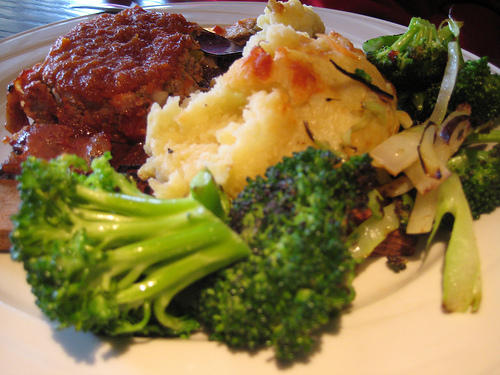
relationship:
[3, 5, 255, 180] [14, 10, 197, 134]
tomato sauce on meatloaf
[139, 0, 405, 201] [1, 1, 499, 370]
mash potatoes in middle of dish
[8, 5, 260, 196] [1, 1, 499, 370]
stew on dish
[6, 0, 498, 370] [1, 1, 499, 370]
meal on dish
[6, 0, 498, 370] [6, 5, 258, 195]
meal has meat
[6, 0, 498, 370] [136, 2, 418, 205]
meal has mash potatoes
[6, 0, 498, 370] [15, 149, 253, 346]
meal has broccoli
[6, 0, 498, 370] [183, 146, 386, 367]
meal has broccoli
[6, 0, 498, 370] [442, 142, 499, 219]
meal has broccoli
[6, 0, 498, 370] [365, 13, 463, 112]
meal has broccoli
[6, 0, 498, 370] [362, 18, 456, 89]
meal has broccoli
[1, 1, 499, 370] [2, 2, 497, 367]
dish has food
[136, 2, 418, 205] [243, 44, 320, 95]
mash potatoes have spots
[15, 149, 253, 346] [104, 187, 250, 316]
broccoli has stem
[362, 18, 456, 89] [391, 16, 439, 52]
broccoli has stem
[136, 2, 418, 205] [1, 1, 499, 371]
mash potatoes on plate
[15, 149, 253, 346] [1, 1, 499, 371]
broccoli crown on plate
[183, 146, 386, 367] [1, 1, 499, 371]
broccoli crown on plate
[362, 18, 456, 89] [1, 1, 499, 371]
broccoli crown on plate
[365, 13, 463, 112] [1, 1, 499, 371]
broccoli on plate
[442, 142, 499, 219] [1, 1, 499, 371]
broccoli crown on plate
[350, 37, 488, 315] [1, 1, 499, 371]
onions on plate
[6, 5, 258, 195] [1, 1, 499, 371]
meat on plate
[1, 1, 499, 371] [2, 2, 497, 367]
plate has food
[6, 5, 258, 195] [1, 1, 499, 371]
mince meat on plate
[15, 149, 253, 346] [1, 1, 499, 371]
broccoli crown around plate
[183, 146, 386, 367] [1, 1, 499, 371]
broccoli crown around plate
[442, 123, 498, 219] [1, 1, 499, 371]
broccoli crown around plate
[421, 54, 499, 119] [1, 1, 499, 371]
broccoli crown around plate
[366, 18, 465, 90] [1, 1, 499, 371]
broccoli crown around plate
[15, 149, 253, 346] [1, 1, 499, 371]
broccoli on plate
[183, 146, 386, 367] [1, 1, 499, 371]
broccoli on plate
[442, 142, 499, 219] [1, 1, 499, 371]
broccoli on plate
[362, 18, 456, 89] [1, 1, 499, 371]
broccoli on plate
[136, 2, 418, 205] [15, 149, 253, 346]
mash potatoes next to broccoli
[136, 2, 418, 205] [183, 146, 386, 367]
mash potatoes next to broccoli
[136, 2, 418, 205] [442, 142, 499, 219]
mash potatoes next to broccoli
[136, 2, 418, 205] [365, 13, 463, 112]
mash potatoes next to broccoli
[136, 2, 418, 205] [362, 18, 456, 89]
mash potatoes next to broccoli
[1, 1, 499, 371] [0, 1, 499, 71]
plate on table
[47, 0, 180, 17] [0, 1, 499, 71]
light shining on table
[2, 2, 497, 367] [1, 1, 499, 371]
food on plate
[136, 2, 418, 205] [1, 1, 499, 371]
mash potatoes in middle of plate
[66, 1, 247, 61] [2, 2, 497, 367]
fork on food